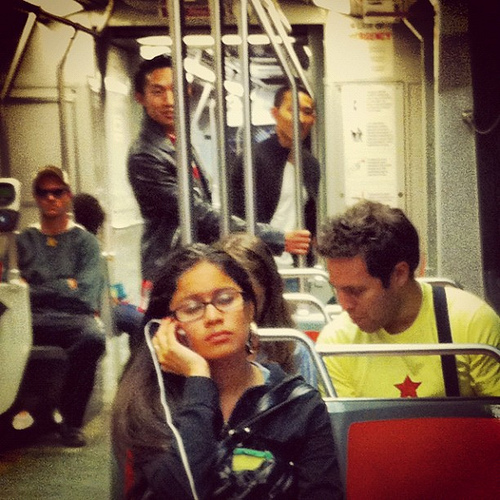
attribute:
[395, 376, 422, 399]
star — red, small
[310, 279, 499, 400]
shirt — yellow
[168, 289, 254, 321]
glasses — paired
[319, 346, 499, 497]
seat — empty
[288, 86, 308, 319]
pole — metal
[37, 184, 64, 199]
sunglasses — paired, dark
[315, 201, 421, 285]
hair — short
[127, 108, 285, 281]
jacket — leather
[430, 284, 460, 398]
strap — black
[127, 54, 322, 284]
men — standing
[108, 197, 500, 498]
people — sitting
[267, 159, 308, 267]
shirt — white